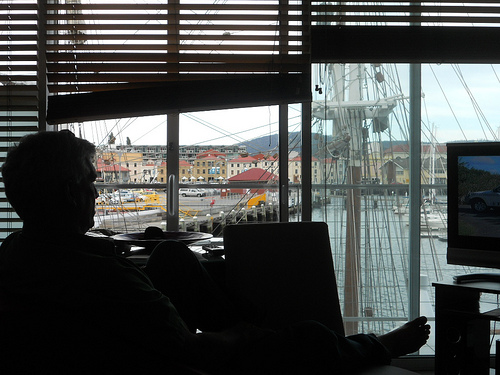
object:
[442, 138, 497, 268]
telelvision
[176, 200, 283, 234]
bridge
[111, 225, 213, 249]
bowl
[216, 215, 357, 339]
chair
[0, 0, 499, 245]
blinds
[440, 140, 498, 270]
monitor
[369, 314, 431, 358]
foot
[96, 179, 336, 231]
dock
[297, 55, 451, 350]
sail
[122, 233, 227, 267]
table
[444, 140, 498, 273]
television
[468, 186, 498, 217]
automobile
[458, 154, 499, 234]
monitor screen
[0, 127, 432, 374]
man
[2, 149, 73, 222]
hair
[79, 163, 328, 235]
harbor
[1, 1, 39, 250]
window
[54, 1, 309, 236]
window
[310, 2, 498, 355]
window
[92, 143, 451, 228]
building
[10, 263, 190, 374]
chair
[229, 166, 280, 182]
top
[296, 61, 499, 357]
boat